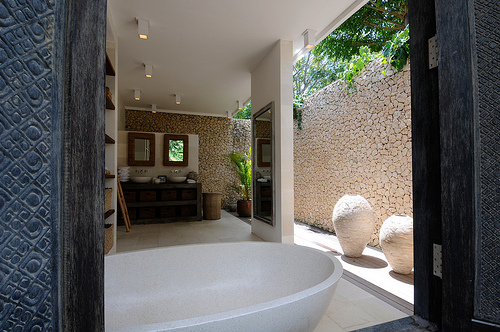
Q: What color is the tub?
A: White.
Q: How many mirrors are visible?
A: 3.